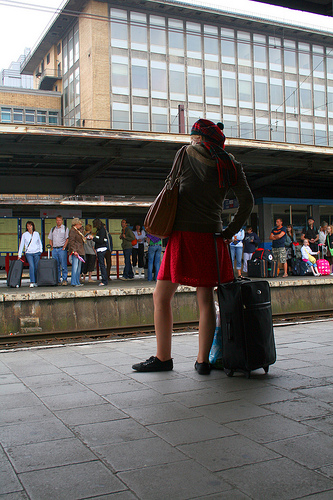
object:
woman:
[284, 224, 297, 276]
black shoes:
[130, 356, 174, 372]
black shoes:
[194, 360, 213, 377]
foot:
[130, 353, 173, 373]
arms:
[269, 231, 285, 241]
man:
[269, 217, 289, 278]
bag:
[303, 246, 316, 264]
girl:
[300, 239, 322, 278]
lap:
[302, 254, 317, 262]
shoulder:
[174, 145, 203, 162]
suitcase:
[316, 242, 331, 278]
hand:
[318, 250, 320, 253]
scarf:
[196, 140, 238, 188]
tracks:
[1, 308, 332, 352]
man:
[119, 219, 138, 281]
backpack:
[131, 232, 137, 246]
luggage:
[7, 257, 24, 288]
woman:
[17, 219, 43, 288]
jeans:
[26, 251, 41, 284]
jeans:
[52, 246, 68, 282]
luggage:
[36, 243, 58, 286]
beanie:
[189, 118, 238, 187]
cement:
[70, 349, 134, 368]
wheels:
[224, 365, 271, 378]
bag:
[143, 142, 187, 239]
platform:
[0, 315, 332, 500]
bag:
[212, 232, 277, 379]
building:
[0, 0, 333, 273]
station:
[0, 177, 333, 295]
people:
[87, 217, 114, 287]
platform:
[0, 274, 333, 338]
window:
[109, 6, 128, 50]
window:
[130, 56, 150, 98]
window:
[187, 66, 203, 103]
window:
[220, 25, 236, 65]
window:
[284, 80, 299, 114]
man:
[48, 214, 70, 287]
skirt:
[156, 229, 234, 287]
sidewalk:
[1, 321, 333, 500]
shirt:
[148, 237, 162, 245]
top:
[167, 141, 254, 240]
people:
[68, 217, 87, 288]